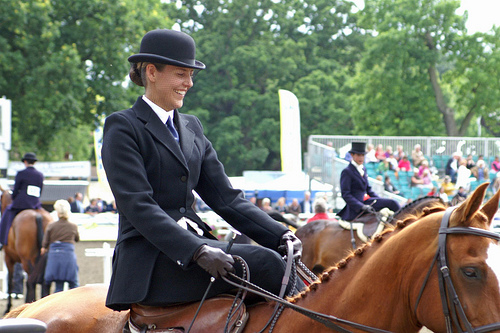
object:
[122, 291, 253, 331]
saddle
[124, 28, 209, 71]
hat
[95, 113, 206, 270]
sleeve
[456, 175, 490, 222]
ear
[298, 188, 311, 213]
fan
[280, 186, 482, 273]
horses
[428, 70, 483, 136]
branch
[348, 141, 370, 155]
hat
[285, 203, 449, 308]
mane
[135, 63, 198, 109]
head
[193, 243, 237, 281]
gloves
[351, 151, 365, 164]
head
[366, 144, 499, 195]
fans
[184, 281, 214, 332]
crop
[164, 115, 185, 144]
tie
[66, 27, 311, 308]
lady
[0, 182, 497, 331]
horse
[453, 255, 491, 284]
horse's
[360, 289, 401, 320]
horse's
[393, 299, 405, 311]
brown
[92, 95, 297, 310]
shirt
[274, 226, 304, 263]
hands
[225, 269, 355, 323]
reins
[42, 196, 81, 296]
person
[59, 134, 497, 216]
group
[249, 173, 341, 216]
spectators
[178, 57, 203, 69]
ribbon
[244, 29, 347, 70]
leaves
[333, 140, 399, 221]
man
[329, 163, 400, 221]
jacket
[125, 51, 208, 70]
brim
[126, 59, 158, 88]
hair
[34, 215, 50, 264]
tail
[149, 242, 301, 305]
pants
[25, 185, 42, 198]
number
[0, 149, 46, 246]
man